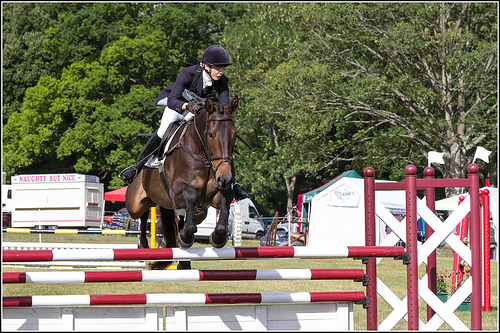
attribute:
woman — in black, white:
[149, 22, 235, 167]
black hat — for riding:
[195, 43, 263, 82]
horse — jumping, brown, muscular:
[144, 121, 235, 248]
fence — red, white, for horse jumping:
[17, 243, 376, 332]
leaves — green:
[394, 49, 407, 59]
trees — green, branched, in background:
[350, 17, 499, 159]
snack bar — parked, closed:
[9, 166, 105, 232]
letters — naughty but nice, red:
[12, 171, 91, 192]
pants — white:
[156, 108, 176, 135]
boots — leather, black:
[129, 139, 155, 165]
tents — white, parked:
[307, 185, 410, 249]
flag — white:
[472, 134, 488, 160]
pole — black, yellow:
[16, 226, 151, 239]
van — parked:
[193, 201, 288, 229]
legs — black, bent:
[159, 181, 246, 243]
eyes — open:
[209, 120, 241, 140]